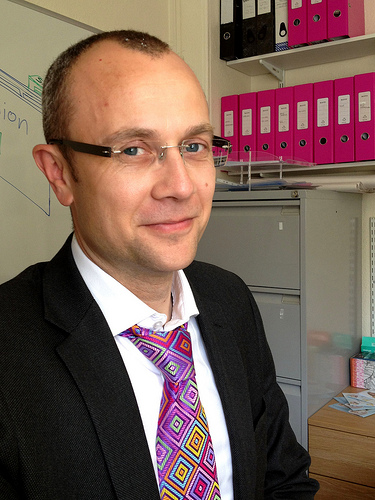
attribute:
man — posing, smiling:
[2, 27, 323, 499]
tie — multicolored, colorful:
[117, 321, 220, 499]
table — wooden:
[302, 382, 373, 500]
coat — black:
[0, 230, 318, 498]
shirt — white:
[62, 230, 237, 497]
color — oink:
[219, 71, 374, 163]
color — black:
[216, 1, 277, 63]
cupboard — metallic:
[187, 182, 365, 480]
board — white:
[3, 1, 112, 280]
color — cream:
[22, 1, 178, 53]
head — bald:
[32, 24, 222, 275]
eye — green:
[123, 141, 150, 162]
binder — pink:
[217, 93, 242, 164]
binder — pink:
[236, 89, 259, 164]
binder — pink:
[256, 84, 276, 161]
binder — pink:
[276, 86, 294, 166]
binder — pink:
[293, 83, 314, 167]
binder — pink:
[313, 77, 336, 166]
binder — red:
[285, 0, 309, 50]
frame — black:
[43, 130, 235, 179]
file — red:
[326, 0, 368, 44]